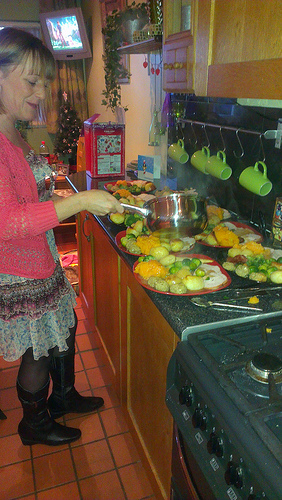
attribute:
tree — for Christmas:
[53, 88, 86, 153]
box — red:
[83, 106, 125, 177]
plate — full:
[106, 179, 156, 197]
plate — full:
[115, 224, 197, 254]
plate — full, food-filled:
[131, 253, 227, 296]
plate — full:
[197, 214, 265, 242]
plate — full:
[226, 242, 280, 280]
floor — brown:
[0, 217, 163, 498]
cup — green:
[237, 160, 275, 196]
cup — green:
[206, 148, 231, 180]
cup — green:
[190, 145, 208, 174]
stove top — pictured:
[214, 335, 240, 381]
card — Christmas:
[135, 152, 161, 183]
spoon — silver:
[196, 292, 272, 318]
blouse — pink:
[2, 126, 82, 285]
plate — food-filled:
[195, 219, 262, 247]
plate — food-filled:
[115, 229, 194, 255]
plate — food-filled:
[103, 181, 156, 194]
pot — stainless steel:
[120, 193, 207, 239]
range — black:
[211, 328, 281, 400]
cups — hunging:
[159, 131, 275, 206]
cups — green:
[163, 137, 275, 196]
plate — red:
[131, 276, 230, 308]